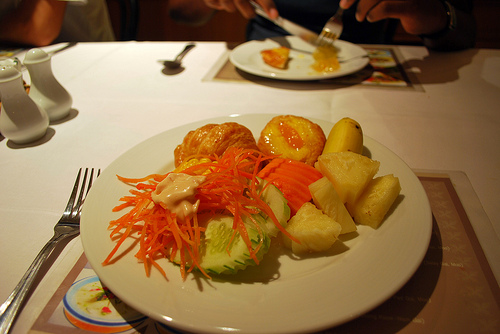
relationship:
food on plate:
[151, 138, 380, 249] [80, 114, 439, 333]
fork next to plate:
[3, 168, 102, 332] [80, 114, 439, 333]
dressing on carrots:
[159, 176, 197, 214] [116, 160, 272, 264]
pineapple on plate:
[305, 153, 397, 230] [80, 114, 439, 333]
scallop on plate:
[251, 114, 319, 159] [80, 114, 439, 333]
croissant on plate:
[181, 127, 252, 153] [80, 114, 439, 333]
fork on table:
[3, 168, 102, 332] [1, 44, 498, 333]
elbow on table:
[9, 4, 66, 43] [1, 44, 498, 333]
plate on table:
[80, 114, 439, 333] [1, 44, 498, 333]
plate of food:
[80, 114, 439, 333] [151, 138, 380, 249]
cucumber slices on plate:
[188, 218, 271, 269] [80, 114, 439, 333]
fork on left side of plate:
[3, 168, 102, 332] [80, 114, 439, 333]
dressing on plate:
[159, 176, 197, 214] [80, 114, 439, 333]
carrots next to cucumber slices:
[116, 160, 272, 264] [188, 218, 271, 269]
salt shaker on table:
[2, 64, 49, 142] [1, 44, 498, 333]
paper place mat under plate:
[212, 46, 420, 92] [236, 40, 366, 81]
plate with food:
[80, 114, 439, 333] [151, 138, 380, 249]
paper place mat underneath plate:
[212, 46, 420, 92] [236, 40, 366, 81]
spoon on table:
[160, 43, 195, 74] [1, 44, 498, 333]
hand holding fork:
[342, 0, 439, 28] [314, 8, 350, 44]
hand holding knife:
[218, 2, 284, 18] [263, 8, 329, 46]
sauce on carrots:
[159, 176, 197, 214] [116, 160, 272, 264]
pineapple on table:
[305, 153, 397, 230] [1, 44, 498, 333]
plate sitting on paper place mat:
[236, 40, 366, 81] [212, 46, 420, 92]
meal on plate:
[151, 138, 380, 249] [80, 114, 439, 333]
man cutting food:
[240, 2, 406, 43] [264, 43, 337, 68]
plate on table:
[236, 40, 366, 81] [1, 44, 498, 333]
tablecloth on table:
[4, 44, 496, 333] [1, 44, 498, 333]